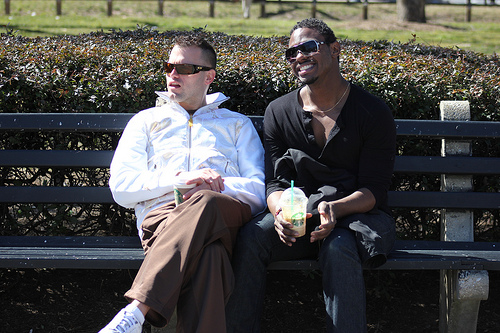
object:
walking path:
[0, 1, 498, 21]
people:
[235, 18, 394, 332]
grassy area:
[0, 1, 499, 55]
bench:
[0, 101, 498, 332]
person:
[99, 37, 266, 333]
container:
[279, 179, 308, 237]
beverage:
[279, 219, 304, 238]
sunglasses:
[285, 39, 331, 61]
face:
[286, 27, 330, 84]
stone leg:
[439, 268, 489, 333]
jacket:
[110, 92, 266, 230]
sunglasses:
[162, 61, 213, 75]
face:
[166, 46, 205, 103]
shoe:
[97, 310, 141, 333]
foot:
[97, 307, 144, 333]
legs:
[104, 190, 251, 324]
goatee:
[300, 77, 316, 84]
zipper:
[187, 111, 194, 179]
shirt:
[263, 84, 396, 216]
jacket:
[274, 148, 396, 267]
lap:
[236, 221, 283, 257]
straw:
[289, 178, 294, 213]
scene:
[1, 1, 499, 332]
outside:
[1, 1, 499, 332]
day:
[1, 2, 499, 333]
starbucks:
[290, 211, 305, 227]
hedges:
[1, 24, 499, 241]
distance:
[1, 1, 498, 20]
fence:
[1, 1, 499, 22]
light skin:
[164, 38, 224, 201]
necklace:
[300, 82, 350, 114]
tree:
[396, 1, 426, 23]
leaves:
[5, 43, 33, 72]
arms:
[109, 108, 172, 205]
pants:
[233, 208, 366, 332]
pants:
[124, 188, 253, 333]